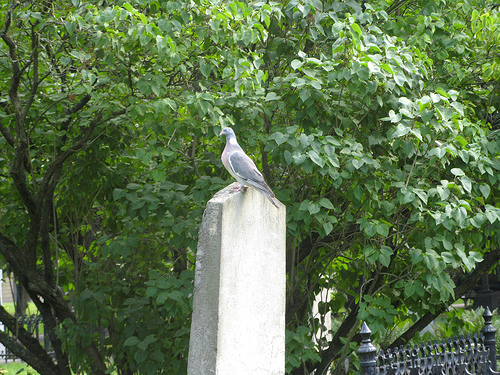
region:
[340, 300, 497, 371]
the fence is wrought iron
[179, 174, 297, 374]
this is a monument of some type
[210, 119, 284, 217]
the pigeon is sitting atop the monument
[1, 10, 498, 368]
the trees are green and beautiful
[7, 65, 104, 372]
the branches look almost black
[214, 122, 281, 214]
the pigeon has gray and white feathers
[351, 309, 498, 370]
the fence is black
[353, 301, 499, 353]
the finials on the fence are pointed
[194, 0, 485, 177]
the sun is shining on the trees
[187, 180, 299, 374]
there is no writing on this side of the stone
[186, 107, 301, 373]
A bird standing by itself.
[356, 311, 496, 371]
The fence is black.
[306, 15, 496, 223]
Green leaves on the tree.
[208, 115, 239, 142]
The head of a bird.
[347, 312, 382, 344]
The pointy part of a fence.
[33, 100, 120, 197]
A branch on a tree.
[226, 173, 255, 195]
The feet of a bird.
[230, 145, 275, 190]
The wing of a bird.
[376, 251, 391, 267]
A green leaf.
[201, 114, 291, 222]
A gray colored bird.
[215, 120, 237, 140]
the head of a bird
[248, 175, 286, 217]
the tail of a bird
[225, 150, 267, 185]
the wing of a bird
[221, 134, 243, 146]
the neck of a bird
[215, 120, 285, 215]
a bird on the pillar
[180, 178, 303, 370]
a gray cement pillar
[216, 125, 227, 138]
the beak of a bird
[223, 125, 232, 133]
the eye of a bird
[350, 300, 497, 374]
a black metal fence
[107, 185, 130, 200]
a green leaf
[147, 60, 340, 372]
a bird on a pole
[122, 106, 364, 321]
a bird that is outside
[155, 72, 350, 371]
a bird on a cement pole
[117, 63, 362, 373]
a bird on a sunny day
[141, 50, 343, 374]
a bird during the day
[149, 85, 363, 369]
a bird resting on pole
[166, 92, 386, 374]
a bird resting on cement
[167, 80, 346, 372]
a bird on a cement structure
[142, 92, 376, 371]
a bird resting during the day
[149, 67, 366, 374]
a bird perched on a structure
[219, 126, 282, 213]
a pigeon perched on a stone slab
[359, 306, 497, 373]
an iron fence and post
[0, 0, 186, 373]
large trees behind the stone slab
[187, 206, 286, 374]
the concrete slab has chips on it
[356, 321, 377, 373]
the fence post is metal painted black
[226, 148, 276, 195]
the pigeon has white trim on his wing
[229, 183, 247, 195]
the pigeons legs are pink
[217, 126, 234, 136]
the pigeons head is grey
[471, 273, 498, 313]
a concrete fountain is behind the fence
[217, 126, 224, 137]
the pigeons beak is pink